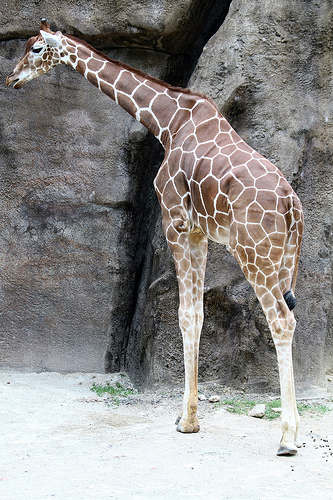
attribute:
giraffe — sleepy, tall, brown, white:
[8, 17, 301, 458]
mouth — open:
[8, 76, 21, 88]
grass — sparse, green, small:
[102, 392, 144, 430]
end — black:
[284, 292, 296, 313]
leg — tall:
[163, 219, 205, 421]